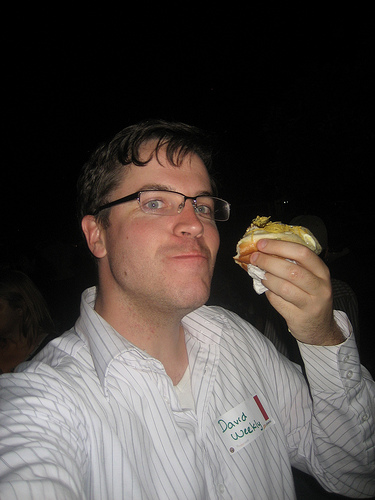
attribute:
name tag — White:
[209, 388, 277, 458]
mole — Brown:
[113, 268, 135, 280]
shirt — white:
[0, 291, 373, 497]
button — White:
[342, 353, 349, 362]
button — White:
[346, 369, 353, 378]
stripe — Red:
[252, 393, 269, 420]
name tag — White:
[211, 392, 275, 454]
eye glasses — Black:
[92, 188, 231, 221]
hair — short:
[88, 125, 151, 186]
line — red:
[251, 393, 268, 421]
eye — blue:
[194, 202, 212, 216]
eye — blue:
[142, 197, 165, 210]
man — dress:
[2, 121, 359, 488]